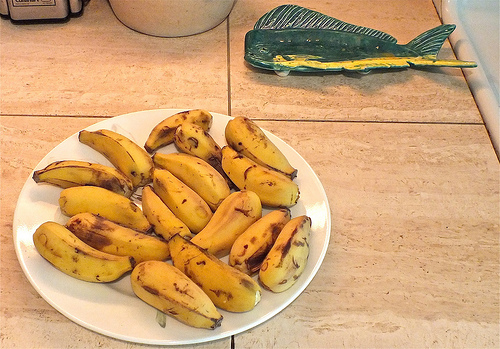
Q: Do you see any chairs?
A: No, there are no chairs.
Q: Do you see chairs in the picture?
A: No, there are no chairs.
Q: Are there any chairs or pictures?
A: No, there are no chairs or pictures.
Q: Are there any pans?
A: Yes, there is a pan.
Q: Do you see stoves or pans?
A: Yes, there is a pan.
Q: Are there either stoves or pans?
A: Yes, there is a pan.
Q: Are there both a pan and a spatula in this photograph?
A: No, there is a pan but no spatulas.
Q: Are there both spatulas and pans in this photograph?
A: No, there is a pan but no spatulas.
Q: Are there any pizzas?
A: No, there are no pizzas.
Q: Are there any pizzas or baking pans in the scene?
A: No, there are no pizzas or baking pans.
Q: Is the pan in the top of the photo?
A: Yes, the pan is in the top of the image.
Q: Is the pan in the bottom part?
A: No, the pan is in the top of the image.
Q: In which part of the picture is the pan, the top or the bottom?
A: The pan is in the top of the image.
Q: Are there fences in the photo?
A: No, there are no fences.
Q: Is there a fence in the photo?
A: No, there are no fences.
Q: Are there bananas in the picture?
A: Yes, there is a banana.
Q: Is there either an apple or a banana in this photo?
A: Yes, there is a banana.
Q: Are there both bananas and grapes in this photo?
A: No, there is a banana but no grapes.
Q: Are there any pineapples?
A: No, there are no pineapples.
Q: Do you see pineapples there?
A: No, there are no pineapples.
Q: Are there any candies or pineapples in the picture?
A: No, there are no pineapples or candies.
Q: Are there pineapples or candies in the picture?
A: No, there are no pineapples or candies.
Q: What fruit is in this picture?
A: The fruit is a banana.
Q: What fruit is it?
A: The fruit is a banana.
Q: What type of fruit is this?
A: This is a banana.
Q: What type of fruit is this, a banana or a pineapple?
A: This is a banana.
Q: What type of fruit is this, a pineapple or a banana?
A: This is a banana.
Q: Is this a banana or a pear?
A: This is a banana.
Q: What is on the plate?
A: The banana is on the plate.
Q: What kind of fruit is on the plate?
A: The fruit is a banana.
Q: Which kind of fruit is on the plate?
A: The fruit is a banana.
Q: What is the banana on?
A: The banana is on the plate.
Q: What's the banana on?
A: The banana is on the plate.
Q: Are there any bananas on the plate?
A: Yes, there is a banana on the plate.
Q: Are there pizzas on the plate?
A: No, there is a banana on the plate.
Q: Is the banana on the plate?
A: Yes, the banana is on the plate.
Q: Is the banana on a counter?
A: No, the banana is on the plate.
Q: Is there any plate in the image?
A: Yes, there is a plate.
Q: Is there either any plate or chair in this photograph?
A: Yes, there is a plate.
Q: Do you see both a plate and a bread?
A: No, there is a plate but no breads.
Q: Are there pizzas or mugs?
A: No, there are no pizzas or mugs.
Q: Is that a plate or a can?
A: That is a plate.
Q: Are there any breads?
A: No, there are no breads.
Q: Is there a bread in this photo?
A: No, there is no breads.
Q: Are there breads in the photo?
A: No, there are no breads.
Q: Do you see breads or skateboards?
A: No, there are no breads or skateboards.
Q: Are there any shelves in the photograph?
A: No, there are no shelves.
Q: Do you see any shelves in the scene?
A: No, there are no shelves.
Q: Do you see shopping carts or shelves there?
A: No, there are no shelves or shopping carts.